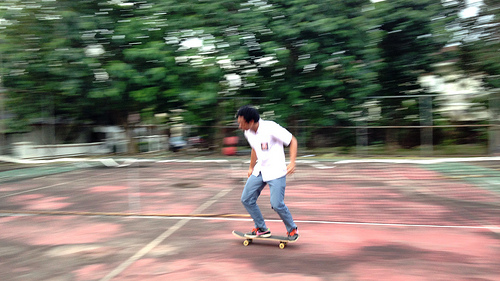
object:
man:
[231, 108, 298, 239]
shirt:
[243, 117, 291, 184]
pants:
[241, 175, 297, 233]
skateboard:
[230, 227, 300, 247]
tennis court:
[1, 155, 500, 278]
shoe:
[245, 226, 274, 240]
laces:
[252, 230, 254, 232]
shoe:
[286, 227, 300, 239]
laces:
[292, 233, 294, 236]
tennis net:
[0, 154, 500, 229]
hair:
[236, 105, 261, 125]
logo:
[261, 142, 270, 151]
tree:
[2, 2, 222, 137]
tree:
[220, 1, 499, 138]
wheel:
[242, 240, 250, 247]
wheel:
[278, 242, 286, 249]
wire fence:
[2, 85, 499, 161]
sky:
[417, 73, 481, 97]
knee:
[241, 197, 255, 208]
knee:
[271, 203, 286, 211]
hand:
[246, 169, 256, 179]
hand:
[286, 159, 298, 177]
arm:
[271, 122, 302, 176]